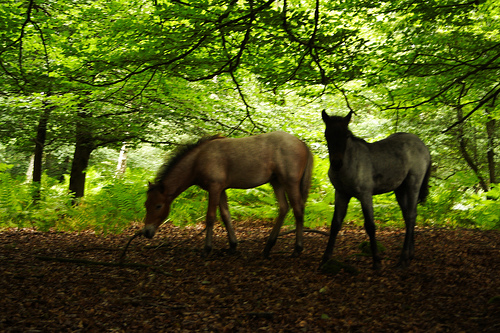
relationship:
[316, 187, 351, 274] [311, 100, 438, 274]
front leg of horse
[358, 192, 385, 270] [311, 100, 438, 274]
front leg of horse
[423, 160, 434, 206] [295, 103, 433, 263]
tail of horse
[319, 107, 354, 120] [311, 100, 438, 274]
ears of horse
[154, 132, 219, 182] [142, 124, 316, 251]
fur on horse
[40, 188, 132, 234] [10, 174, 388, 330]
vegetation on ground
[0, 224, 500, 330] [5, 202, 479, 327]
leaves on ground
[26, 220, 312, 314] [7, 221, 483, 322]
sticks on ground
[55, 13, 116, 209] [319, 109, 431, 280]
tree surrounding animal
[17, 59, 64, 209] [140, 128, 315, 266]
tree surrounding animal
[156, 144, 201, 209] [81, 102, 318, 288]
neck on horse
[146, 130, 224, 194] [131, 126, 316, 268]
mane on horse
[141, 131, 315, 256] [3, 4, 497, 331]
horse in woods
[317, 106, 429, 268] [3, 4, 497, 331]
horse in woods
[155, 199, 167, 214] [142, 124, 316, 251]
eye on horse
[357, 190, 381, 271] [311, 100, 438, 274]
front leg on horse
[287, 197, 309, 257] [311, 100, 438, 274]
leg on horse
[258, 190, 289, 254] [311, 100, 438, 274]
leg on horse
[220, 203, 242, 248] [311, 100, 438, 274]
leg on horse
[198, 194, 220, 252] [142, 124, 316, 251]
leg on horse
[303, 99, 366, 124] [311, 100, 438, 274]
ears on horse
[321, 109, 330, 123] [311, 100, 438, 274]
ears on horse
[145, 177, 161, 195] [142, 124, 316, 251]
ears on horse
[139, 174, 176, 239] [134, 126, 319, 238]
head on horse